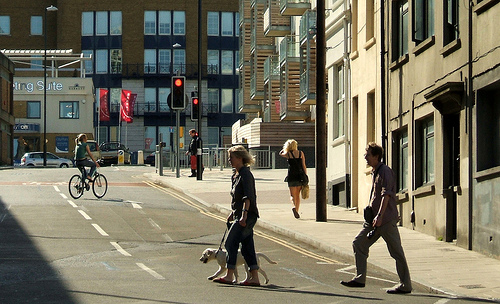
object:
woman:
[280, 138, 309, 219]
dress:
[285, 158, 309, 181]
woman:
[213, 144, 259, 285]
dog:
[200, 249, 275, 283]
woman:
[74, 134, 99, 193]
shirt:
[75, 142, 89, 160]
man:
[339, 142, 411, 295]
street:
[1, 167, 461, 303]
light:
[171, 76, 185, 110]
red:
[175, 79, 183, 86]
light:
[191, 96, 200, 119]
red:
[193, 97, 199, 105]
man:
[187, 128, 199, 178]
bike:
[69, 166, 108, 201]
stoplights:
[171, 76, 198, 120]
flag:
[120, 90, 131, 123]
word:
[37, 81, 63, 92]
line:
[54, 186, 165, 280]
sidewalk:
[145, 170, 497, 301]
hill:
[0, 164, 499, 301]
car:
[21, 152, 72, 167]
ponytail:
[74, 136, 80, 145]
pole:
[315, 0, 326, 223]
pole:
[116, 89, 123, 149]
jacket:
[188, 136, 200, 153]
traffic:
[59, 135, 109, 199]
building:
[232, 2, 315, 168]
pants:
[190, 151, 200, 172]